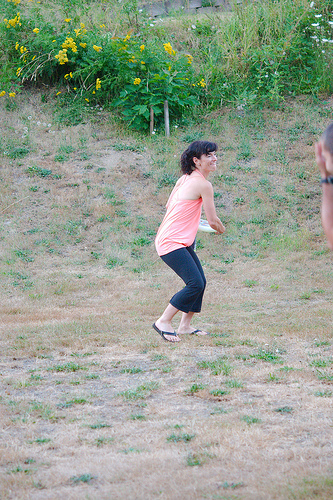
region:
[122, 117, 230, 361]
aperson playing frisbee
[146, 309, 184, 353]
the sadles are black in colour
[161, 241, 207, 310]
the trouser is black in colour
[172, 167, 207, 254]
the vest is orange in colour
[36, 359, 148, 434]
the grass is scarsely growing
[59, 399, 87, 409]
the grass is green in colour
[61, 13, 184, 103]
the plants are green in colour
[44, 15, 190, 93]
the plant has yellow flowers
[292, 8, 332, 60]
the flowers are white in colour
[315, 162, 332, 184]
the man has a watch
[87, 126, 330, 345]
a woman plahying frisbee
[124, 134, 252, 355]
she is enjoying herself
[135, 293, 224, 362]
this woman is wearing sandals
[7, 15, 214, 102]
the flowers are yellow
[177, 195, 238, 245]
she is about to fling the frisbee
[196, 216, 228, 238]
the frisbee is white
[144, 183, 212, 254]
she is wearing a pink shirt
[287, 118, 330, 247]
this person cannot be fully seen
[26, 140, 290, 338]
sparse grass is on the ground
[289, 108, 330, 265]
this person is ready to receive the frisbee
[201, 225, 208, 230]
A frisbee in the hand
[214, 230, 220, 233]
Hand wrapped around frisbee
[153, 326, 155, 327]
Heel lifted from the ground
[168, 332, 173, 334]
The strap of the sandal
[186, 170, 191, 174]
Hair touching the back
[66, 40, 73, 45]
Yellow flowers in the bush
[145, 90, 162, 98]
Bush with green leaves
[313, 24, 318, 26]
White flower on a bush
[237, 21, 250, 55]
Long grass sticking out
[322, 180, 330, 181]
A watch strap on the wrist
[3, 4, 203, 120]
yellow flowers of weeds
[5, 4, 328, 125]
tall weeds on hill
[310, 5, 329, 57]
white flowers of weeds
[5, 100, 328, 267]
patches of grass on hill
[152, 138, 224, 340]
woman standing on ground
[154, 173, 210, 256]
pink top on woman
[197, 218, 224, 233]
white frisbee in hand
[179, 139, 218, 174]
black hair on head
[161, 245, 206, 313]
blue capri pants on woman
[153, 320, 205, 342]
flip flops on feet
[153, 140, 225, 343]
Woman about to throw a Frisbee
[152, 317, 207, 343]
Flip-flops on woman's feet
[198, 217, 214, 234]
White Frisbee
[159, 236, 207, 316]
Black capris on woman's legs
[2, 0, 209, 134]
Yellow flowers on the bushes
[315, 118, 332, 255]
Man with hand over his face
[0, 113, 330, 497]
Patches of green grass amidst the brown grass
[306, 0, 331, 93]
White flowers growing in the field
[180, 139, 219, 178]
Woman's black hair pulled into a ponytail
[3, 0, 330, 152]
Flowers and weeds at edge of field